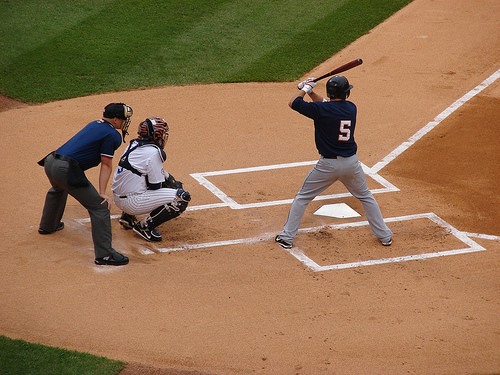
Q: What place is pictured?
A: It is a field.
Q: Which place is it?
A: It is a field.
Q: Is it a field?
A: Yes, it is a field.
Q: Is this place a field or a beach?
A: It is a field.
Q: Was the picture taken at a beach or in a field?
A: It was taken at a field.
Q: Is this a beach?
A: No, it is a field.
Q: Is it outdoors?
A: Yes, it is outdoors.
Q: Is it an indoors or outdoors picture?
A: It is outdoors.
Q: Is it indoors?
A: No, it is outdoors.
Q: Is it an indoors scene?
A: No, it is outdoors.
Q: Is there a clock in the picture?
A: No, there are no clocks.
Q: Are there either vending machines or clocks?
A: No, there are no clocks or vending machines.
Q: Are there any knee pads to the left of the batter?
A: Yes, there are knee pads to the left of the batter.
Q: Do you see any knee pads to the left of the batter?
A: Yes, there are knee pads to the left of the batter.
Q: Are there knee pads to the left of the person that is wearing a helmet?
A: Yes, there are knee pads to the left of the batter.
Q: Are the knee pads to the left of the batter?
A: Yes, the knee pads are to the left of the batter.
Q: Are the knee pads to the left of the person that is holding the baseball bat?
A: Yes, the knee pads are to the left of the batter.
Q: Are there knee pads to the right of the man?
A: Yes, there are knee pads to the right of the man.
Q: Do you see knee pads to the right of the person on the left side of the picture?
A: Yes, there are knee pads to the right of the man.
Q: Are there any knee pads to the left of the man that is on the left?
A: No, the knee pads are to the right of the man.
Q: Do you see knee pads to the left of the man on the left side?
A: No, the knee pads are to the right of the man.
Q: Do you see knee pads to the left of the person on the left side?
A: No, the knee pads are to the right of the man.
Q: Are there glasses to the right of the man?
A: No, there are knee pads to the right of the man.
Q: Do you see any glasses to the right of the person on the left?
A: No, there are knee pads to the right of the man.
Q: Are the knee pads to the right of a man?
A: Yes, the knee pads are to the right of a man.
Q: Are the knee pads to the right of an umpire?
A: No, the knee pads are to the right of a man.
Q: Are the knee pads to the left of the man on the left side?
A: No, the knee pads are to the right of the man.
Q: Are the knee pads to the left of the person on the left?
A: No, the knee pads are to the right of the man.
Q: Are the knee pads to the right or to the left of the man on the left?
A: The knee pads are to the right of the man.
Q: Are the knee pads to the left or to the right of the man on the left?
A: The knee pads are to the right of the man.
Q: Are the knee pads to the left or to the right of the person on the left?
A: The knee pads are to the right of the man.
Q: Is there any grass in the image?
A: Yes, there is grass.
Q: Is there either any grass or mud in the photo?
A: Yes, there is grass.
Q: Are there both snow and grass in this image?
A: No, there is grass but no snow.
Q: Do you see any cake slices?
A: No, there are no cake slices.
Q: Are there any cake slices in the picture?
A: No, there are no cake slices.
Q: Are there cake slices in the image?
A: No, there are no cake slices.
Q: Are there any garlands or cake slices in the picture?
A: No, there are no cake slices or garlands.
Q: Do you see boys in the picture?
A: No, there are no boys.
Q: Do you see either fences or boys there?
A: No, there are no boys or fences.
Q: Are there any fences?
A: No, there are no fences.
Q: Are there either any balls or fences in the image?
A: No, there are no fences or balls.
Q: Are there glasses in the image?
A: No, there are no glasses.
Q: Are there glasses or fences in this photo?
A: No, there are no glasses or fences.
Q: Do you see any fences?
A: No, there are no fences.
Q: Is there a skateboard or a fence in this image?
A: No, there are no fences or skateboards.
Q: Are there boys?
A: No, there are no boys.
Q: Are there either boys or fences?
A: No, there are no boys or fences.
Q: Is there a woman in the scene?
A: No, there are no women.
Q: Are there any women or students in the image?
A: No, there are no women or students.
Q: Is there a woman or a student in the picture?
A: No, there are no women or students.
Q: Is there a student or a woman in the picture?
A: No, there are no women or students.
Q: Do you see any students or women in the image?
A: No, there are no women or students.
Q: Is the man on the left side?
A: Yes, the man is on the left of the image.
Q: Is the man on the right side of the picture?
A: No, the man is on the left of the image.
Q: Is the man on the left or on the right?
A: The man is on the left of the image.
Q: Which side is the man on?
A: The man is on the left of the image.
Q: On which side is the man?
A: The man is on the left of the image.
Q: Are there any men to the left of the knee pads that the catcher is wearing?
A: Yes, there is a man to the left of the knee pads.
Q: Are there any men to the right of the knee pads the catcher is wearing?
A: No, the man is to the left of the knee pads.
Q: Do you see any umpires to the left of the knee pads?
A: No, there is a man to the left of the knee pads.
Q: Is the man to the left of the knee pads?
A: Yes, the man is to the left of the knee pads.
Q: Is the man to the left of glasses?
A: No, the man is to the left of the knee pads.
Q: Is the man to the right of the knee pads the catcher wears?
A: No, the man is to the left of the knee pads.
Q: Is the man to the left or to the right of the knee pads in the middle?
A: The man is to the left of the knee pads.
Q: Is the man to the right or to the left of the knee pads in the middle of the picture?
A: The man is to the left of the knee pads.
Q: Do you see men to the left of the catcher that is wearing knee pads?
A: Yes, there is a man to the left of the catcher.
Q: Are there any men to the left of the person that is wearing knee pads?
A: Yes, there is a man to the left of the catcher.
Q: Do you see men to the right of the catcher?
A: No, the man is to the left of the catcher.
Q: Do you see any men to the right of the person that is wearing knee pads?
A: No, the man is to the left of the catcher.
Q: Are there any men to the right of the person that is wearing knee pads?
A: No, the man is to the left of the catcher.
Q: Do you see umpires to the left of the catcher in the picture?
A: No, there is a man to the left of the catcher.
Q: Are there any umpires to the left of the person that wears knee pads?
A: No, there is a man to the left of the catcher.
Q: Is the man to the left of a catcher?
A: Yes, the man is to the left of a catcher.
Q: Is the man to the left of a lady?
A: No, the man is to the left of a catcher.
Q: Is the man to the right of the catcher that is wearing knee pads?
A: No, the man is to the left of the catcher.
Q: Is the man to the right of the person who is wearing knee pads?
A: No, the man is to the left of the catcher.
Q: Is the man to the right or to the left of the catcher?
A: The man is to the left of the catcher.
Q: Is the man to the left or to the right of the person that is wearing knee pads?
A: The man is to the left of the catcher.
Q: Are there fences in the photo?
A: No, there are no fences.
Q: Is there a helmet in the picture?
A: Yes, there is a helmet.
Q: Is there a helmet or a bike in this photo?
A: Yes, there is a helmet.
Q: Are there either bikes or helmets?
A: Yes, there is a helmet.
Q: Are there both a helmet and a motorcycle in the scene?
A: No, there is a helmet but no motorcycles.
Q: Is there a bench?
A: No, there are no benches.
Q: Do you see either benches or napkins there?
A: No, there are no benches or napkins.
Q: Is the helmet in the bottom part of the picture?
A: No, the helmet is in the top of the image.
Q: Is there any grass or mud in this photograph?
A: Yes, there is grass.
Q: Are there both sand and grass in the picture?
A: No, there is grass but no sand.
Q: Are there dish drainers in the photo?
A: No, there are no dish drainers.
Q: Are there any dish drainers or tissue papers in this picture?
A: No, there are no dish drainers or tissue papers.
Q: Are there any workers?
A: No, there are no workers.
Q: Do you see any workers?
A: No, there are no workers.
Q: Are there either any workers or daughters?
A: No, there are no workers or daughters.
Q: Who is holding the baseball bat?
A: The batter is holding the baseball bat.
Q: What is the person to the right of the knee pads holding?
A: The batter is holding the baseball bat.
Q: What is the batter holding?
A: The batter is holding the baseball bat.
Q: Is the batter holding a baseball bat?
A: Yes, the batter is holding a baseball bat.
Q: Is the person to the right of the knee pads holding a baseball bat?
A: Yes, the batter is holding a baseball bat.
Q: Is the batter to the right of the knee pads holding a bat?
A: No, the batter is holding a baseball bat.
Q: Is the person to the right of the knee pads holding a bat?
A: No, the batter is holding a baseball bat.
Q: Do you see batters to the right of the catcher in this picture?
A: Yes, there is a batter to the right of the catcher.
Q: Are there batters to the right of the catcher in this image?
A: Yes, there is a batter to the right of the catcher.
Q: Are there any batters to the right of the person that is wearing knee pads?
A: Yes, there is a batter to the right of the catcher.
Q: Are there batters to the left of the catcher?
A: No, the batter is to the right of the catcher.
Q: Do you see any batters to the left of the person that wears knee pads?
A: No, the batter is to the right of the catcher.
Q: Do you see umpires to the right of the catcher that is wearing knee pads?
A: No, there is a batter to the right of the catcher.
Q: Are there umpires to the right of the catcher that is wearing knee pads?
A: No, there is a batter to the right of the catcher.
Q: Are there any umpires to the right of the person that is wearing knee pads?
A: No, there is a batter to the right of the catcher.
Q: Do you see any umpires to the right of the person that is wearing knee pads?
A: No, there is a batter to the right of the catcher.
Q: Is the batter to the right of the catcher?
A: Yes, the batter is to the right of the catcher.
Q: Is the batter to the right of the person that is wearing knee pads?
A: Yes, the batter is to the right of the catcher.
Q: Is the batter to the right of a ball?
A: No, the batter is to the right of the catcher.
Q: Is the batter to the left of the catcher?
A: No, the batter is to the right of the catcher.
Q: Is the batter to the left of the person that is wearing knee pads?
A: No, the batter is to the right of the catcher.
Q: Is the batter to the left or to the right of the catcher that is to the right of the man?
A: The batter is to the right of the catcher.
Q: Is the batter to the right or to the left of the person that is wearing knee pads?
A: The batter is to the right of the catcher.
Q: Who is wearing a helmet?
A: The batter is wearing a helmet.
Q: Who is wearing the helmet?
A: The batter is wearing a helmet.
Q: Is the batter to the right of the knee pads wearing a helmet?
A: Yes, the batter is wearing a helmet.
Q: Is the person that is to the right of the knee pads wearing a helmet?
A: Yes, the batter is wearing a helmet.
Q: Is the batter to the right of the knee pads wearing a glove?
A: No, the batter is wearing a helmet.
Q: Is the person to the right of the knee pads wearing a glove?
A: No, the batter is wearing a helmet.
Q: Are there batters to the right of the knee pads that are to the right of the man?
A: Yes, there is a batter to the right of the knee pads.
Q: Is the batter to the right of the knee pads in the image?
A: Yes, the batter is to the right of the knee pads.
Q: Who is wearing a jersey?
A: The batter is wearing a jersey.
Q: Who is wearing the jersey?
A: The batter is wearing a jersey.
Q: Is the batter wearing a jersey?
A: Yes, the batter is wearing a jersey.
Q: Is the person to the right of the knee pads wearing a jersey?
A: Yes, the batter is wearing a jersey.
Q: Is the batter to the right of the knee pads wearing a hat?
A: No, the batter is wearing a jersey.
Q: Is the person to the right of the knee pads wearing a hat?
A: No, the batter is wearing a jersey.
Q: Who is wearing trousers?
A: The batter is wearing trousers.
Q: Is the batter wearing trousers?
A: Yes, the batter is wearing trousers.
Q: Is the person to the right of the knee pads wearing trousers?
A: Yes, the batter is wearing trousers.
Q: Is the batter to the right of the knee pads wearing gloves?
A: No, the batter is wearing trousers.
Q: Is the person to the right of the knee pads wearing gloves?
A: No, the batter is wearing trousers.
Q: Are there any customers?
A: No, there are no customers.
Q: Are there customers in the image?
A: No, there are no customers.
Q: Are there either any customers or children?
A: No, there are no customers or children.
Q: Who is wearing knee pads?
A: The catcher is wearing knee pads.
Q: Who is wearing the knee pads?
A: The catcher is wearing knee pads.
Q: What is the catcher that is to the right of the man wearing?
A: The catcher is wearing knee pads.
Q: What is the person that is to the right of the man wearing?
A: The catcher is wearing knee pads.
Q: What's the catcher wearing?
A: The catcher is wearing knee pads.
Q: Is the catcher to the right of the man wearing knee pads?
A: Yes, the catcher is wearing knee pads.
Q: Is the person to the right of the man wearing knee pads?
A: Yes, the catcher is wearing knee pads.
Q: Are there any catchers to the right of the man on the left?
A: Yes, there is a catcher to the right of the man.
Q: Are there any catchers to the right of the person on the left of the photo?
A: Yes, there is a catcher to the right of the man.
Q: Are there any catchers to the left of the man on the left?
A: No, the catcher is to the right of the man.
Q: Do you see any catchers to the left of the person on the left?
A: No, the catcher is to the right of the man.